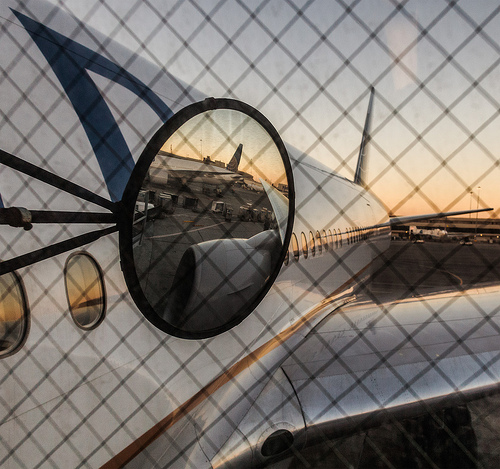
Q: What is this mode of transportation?
A: Airplane.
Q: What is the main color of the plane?
A: White.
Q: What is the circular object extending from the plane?
A: Mirror.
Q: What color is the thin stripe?
A: Gold.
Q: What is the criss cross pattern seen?
A: A fence.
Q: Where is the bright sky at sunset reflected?
A: Mirror.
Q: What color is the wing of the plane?
A: White.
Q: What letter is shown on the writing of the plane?
A: D.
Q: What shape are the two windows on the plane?
A: Round.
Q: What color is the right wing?
A: White.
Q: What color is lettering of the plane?
A: Blue.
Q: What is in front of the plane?
A: A chain link fence.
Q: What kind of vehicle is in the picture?
A: A plane.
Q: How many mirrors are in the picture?
A: 1.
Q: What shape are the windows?
A: Oval.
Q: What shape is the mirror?
A: Circle.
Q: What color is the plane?
A: White.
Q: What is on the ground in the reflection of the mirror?
A: Baggage trucks.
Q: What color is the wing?
A: Silver.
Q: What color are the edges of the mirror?
A: Black.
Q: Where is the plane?
A: At the airport.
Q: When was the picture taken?
A: During the day.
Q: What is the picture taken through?
A: A window.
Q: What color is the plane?
A: White.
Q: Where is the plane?
A: On the runway.